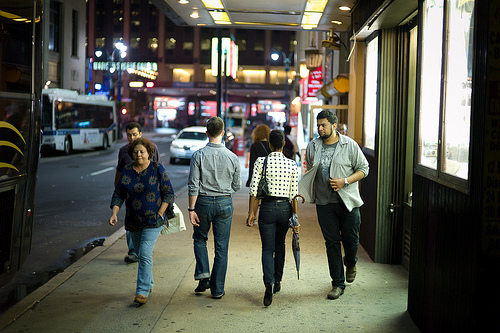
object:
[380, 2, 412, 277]
doorway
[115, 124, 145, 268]
man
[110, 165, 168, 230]
sweater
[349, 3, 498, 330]
storefront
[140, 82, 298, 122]
storefront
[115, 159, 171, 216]
shirt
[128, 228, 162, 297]
jeans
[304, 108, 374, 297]
man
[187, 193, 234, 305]
jeans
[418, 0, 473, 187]
lit store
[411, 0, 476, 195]
window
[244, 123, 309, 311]
woman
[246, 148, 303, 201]
shirt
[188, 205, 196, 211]
watch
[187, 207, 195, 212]
wrist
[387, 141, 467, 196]
ground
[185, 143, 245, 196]
shirt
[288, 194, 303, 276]
umbrella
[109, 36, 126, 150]
streetlight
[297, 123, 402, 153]
wall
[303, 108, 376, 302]
people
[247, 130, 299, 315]
people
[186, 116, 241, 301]
people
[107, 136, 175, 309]
people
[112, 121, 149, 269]
people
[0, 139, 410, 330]
sidewalk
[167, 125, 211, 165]
limousine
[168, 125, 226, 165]
vehicle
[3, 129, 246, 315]
street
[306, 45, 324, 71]
street light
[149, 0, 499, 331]
building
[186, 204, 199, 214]
wristwatch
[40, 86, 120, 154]
tour bus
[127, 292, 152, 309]
shoes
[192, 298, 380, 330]
sidewalk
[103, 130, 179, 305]
woman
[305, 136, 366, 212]
two shirts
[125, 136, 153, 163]
hair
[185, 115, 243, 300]
man